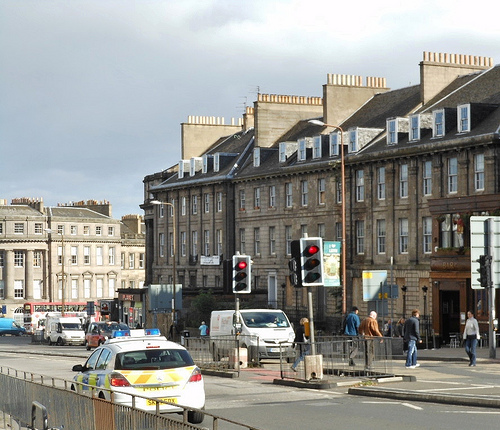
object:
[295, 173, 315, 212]
window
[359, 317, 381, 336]
jacket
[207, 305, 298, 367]
van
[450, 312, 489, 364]
woman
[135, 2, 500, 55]
light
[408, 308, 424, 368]
person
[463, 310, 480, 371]
person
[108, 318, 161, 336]
lights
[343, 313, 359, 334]
jacket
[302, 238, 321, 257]
traffic light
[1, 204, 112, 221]
roof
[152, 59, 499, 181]
roof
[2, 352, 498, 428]
street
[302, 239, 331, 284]
traffic signal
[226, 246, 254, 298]
traffic light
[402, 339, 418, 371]
jeans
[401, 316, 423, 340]
jacket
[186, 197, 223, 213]
window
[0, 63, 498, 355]
building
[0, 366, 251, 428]
barrier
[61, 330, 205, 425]
car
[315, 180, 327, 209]
window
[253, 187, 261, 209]
window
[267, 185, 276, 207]
window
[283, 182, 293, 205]
window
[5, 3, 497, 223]
sky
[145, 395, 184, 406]
license plate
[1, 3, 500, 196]
cloud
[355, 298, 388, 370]
person